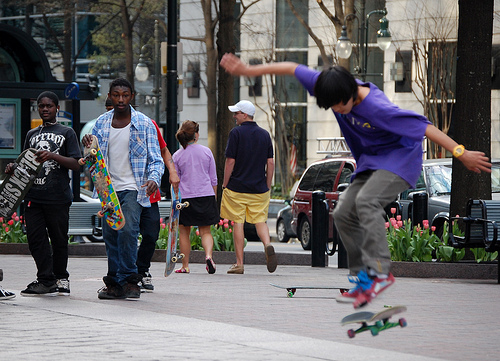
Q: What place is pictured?
A: It is a sidewalk.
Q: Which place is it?
A: It is a sidewalk.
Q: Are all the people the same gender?
A: No, they are both male and female.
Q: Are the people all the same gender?
A: No, they are both male and female.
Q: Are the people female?
A: No, they are both male and female.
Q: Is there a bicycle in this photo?
A: No, there are no bicycles.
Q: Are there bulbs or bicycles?
A: No, there are no bicycles or bulbs.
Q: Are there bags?
A: No, there are no bags.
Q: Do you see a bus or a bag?
A: No, there are no bags or buses.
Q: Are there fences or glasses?
A: No, there are no fences or glasses.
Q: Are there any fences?
A: No, there are no fences.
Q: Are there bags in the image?
A: No, there are no bags.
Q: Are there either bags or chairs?
A: No, there are no bags or chairs.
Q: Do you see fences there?
A: No, there are no fences.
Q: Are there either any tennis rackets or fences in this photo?
A: No, there are no fences or tennis rackets.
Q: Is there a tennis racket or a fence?
A: No, there are no fences or rackets.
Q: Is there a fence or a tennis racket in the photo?
A: No, there are no fences or rackets.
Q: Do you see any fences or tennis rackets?
A: No, there are no fences or tennis rackets.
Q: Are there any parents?
A: No, there are no parents.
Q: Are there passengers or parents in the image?
A: No, there are no parents or passengers.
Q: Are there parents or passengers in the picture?
A: No, there are no parents or passengers.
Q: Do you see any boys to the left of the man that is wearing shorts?
A: Yes, there is a boy to the left of the man.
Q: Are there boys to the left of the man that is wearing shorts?
A: Yes, there is a boy to the left of the man.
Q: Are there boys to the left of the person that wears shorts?
A: Yes, there is a boy to the left of the man.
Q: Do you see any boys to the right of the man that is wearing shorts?
A: No, the boy is to the left of the man.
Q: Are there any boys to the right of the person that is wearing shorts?
A: No, the boy is to the left of the man.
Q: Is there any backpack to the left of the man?
A: No, there is a boy to the left of the man.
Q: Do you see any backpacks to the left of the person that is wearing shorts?
A: No, there is a boy to the left of the man.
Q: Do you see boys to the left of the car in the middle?
A: Yes, there is a boy to the left of the car.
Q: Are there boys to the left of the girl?
A: Yes, there is a boy to the left of the girl.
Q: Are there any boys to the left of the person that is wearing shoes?
A: Yes, there is a boy to the left of the girl.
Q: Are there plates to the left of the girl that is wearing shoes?
A: No, there is a boy to the left of the girl.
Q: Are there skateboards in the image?
A: Yes, there is a skateboard.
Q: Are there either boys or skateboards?
A: Yes, there is a skateboard.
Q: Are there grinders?
A: No, there are no grinders.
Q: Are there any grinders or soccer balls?
A: No, there are no grinders or soccer balls.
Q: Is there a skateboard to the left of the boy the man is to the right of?
A: Yes, there is a skateboard to the left of the boy.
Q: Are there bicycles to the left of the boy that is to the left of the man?
A: No, there is a skateboard to the left of the boy.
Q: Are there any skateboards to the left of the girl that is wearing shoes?
A: Yes, there is a skateboard to the left of the girl.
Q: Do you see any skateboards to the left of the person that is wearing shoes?
A: Yes, there is a skateboard to the left of the girl.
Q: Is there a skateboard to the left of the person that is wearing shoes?
A: Yes, there is a skateboard to the left of the girl.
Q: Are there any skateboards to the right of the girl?
A: No, the skateboard is to the left of the girl.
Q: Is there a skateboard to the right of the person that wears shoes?
A: No, the skateboard is to the left of the girl.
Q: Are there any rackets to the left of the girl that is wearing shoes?
A: No, there is a skateboard to the left of the girl.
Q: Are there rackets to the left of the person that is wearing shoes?
A: No, there is a skateboard to the left of the girl.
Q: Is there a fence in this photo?
A: No, there are no fences.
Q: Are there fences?
A: No, there are no fences.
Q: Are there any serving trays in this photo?
A: No, there are no serving trays.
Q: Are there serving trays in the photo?
A: No, there are no serving trays.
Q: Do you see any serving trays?
A: No, there are no serving trays.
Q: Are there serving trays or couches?
A: No, there are no serving trays or couches.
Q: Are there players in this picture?
A: No, there are no players.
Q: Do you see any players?
A: No, there are no players.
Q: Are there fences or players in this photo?
A: No, there are no players or fences.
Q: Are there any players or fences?
A: No, there are no players or fences.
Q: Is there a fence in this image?
A: No, there are no fences.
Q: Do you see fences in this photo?
A: No, there are no fences.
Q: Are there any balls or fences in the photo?
A: No, there are no fences or balls.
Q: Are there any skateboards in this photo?
A: Yes, there is a skateboard.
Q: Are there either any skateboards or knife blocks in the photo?
A: Yes, there is a skateboard.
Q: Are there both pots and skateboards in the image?
A: No, there is a skateboard but no pots.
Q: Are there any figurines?
A: No, there are no figurines.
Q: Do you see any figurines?
A: No, there are no figurines.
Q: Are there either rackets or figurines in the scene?
A: No, there are no figurines or rackets.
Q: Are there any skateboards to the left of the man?
A: Yes, there is a skateboard to the left of the man.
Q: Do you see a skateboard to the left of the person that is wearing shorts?
A: Yes, there is a skateboard to the left of the man.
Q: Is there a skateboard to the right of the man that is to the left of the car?
A: No, the skateboard is to the left of the man.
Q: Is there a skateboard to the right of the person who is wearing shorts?
A: No, the skateboard is to the left of the man.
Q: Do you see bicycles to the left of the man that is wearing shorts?
A: No, there is a skateboard to the left of the man.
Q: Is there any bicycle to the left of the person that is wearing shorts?
A: No, there is a skateboard to the left of the man.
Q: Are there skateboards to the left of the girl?
A: Yes, there is a skateboard to the left of the girl.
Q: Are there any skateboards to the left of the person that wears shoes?
A: Yes, there is a skateboard to the left of the girl.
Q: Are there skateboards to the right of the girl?
A: No, the skateboard is to the left of the girl.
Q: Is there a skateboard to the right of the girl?
A: No, the skateboard is to the left of the girl.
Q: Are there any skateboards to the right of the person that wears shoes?
A: No, the skateboard is to the left of the girl.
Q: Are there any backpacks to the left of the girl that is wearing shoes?
A: No, there is a skateboard to the left of the girl.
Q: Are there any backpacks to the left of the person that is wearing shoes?
A: No, there is a skateboard to the left of the girl.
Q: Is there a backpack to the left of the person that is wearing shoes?
A: No, there is a skateboard to the left of the girl.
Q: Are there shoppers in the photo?
A: No, there are no shoppers.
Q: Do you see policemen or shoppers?
A: No, there are no shoppers or policemen.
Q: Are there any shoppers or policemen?
A: No, there are no shoppers or policemen.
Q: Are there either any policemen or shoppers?
A: No, there are no shoppers or policemen.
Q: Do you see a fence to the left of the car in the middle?
A: No, there is a man to the left of the car.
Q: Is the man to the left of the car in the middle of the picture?
A: Yes, the man is to the left of the car.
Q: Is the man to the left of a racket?
A: No, the man is to the left of the car.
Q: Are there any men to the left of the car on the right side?
A: Yes, there is a man to the left of the car.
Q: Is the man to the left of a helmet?
A: No, the man is to the left of the car.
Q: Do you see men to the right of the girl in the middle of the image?
A: Yes, there is a man to the right of the girl.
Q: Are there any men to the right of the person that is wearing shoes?
A: Yes, there is a man to the right of the girl.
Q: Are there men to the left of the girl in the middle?
A: No, the man is to the right of the girl.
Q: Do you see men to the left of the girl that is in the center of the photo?
A: No, the man is to the right of the girl.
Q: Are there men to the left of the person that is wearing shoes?
A: No, the man is to the right of the girl.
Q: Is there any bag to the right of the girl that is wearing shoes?
A: No, there is a man to the right of the girl.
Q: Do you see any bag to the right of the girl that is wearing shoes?
A: No, there is a man to the right of the girl.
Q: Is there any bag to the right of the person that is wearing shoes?
A: No, there is a man to the right of the girl.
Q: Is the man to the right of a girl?
A: Yes, the man is to the right of a girl.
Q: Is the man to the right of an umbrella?
A: No, the man is to the right of a girl.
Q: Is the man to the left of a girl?
A: No, the man is to the right of a girl.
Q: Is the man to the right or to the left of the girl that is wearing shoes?
A: The man is to the right of the girl.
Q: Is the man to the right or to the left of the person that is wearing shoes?
A: The man is to the right of the girl.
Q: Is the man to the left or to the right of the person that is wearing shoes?
A: The man is to the right of the girl.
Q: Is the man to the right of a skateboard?
A: Yes, the man is to the right of a skateboard.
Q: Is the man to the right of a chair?
A: No, the man is to the right of a skateboard.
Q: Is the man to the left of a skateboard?
A: No, the man is to the right of a skateboard.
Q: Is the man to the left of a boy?
A: No, the man is to the right of a boy.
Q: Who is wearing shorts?
A: The man is wearing shorts.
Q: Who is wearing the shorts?
A: The man is wearing shorts.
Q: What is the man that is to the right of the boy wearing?
A: The man is wearing shorts.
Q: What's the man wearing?
A: The man is wearing shorts.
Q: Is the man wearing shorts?
A: Yes, the man is wearing shorts.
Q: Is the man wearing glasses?
A: No, the man is wearing shorts.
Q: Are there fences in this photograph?
A: No, there are no fences.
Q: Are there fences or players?
A: No, there are no fences or players.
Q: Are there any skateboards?
A: Yes, there is a skateboard.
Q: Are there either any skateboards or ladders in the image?
A: Yes, there is a skateboard.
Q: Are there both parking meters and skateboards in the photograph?
A: No, there is a skateboard but no parking meters.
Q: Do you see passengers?
A: No, there are no passengers.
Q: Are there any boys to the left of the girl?
A: Yes, there is a boy to the left of the girl.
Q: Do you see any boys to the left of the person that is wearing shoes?
A: Yes, there is a boy to the left of the girl.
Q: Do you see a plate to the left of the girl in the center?
A: No, there is a boy to the left of the girl.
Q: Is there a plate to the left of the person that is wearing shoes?
A: No, there is a boy to the left of the girl.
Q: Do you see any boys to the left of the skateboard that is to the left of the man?
A: Yes, there is a boy to the left of the skateboard.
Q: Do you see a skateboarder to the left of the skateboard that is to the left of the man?
A: No, there is a boy to the left of the skateboard.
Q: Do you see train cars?
A: No, there are no train cars.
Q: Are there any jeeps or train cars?
A: No, there are no train cars or jeeps.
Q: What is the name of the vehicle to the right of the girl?
A: The vehicle is a car.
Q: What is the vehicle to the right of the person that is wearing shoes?
A: The vehicle is a car.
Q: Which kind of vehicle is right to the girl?
A: The vehicle is a car.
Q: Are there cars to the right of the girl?
A: Yes, there is a car to the right of the girl.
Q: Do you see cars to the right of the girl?
A: Yes, there is a car to the right of the girl.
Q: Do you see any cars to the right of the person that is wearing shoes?
A: Yes, there is a car to the right of the girl.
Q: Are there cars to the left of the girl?
A: No, the car is to the right of the girl.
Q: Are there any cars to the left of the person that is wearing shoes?
A: No, the car is to the right of the girl.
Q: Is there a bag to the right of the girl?
A: No, there is a car to the right of the girl.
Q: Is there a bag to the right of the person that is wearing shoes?
A: No, there is a car to the right of the girl.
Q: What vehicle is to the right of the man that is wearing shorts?
A: The vehicle is a car.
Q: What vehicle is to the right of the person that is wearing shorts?
A: The vehicle is a car.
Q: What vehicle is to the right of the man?
A: The vehicle is a car.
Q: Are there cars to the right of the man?
A: Yes, there is a car to the right of the man.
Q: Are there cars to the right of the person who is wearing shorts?
A: Yes, there is a car to the right of the man.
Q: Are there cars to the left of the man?
A: No, the car is to the right of the man.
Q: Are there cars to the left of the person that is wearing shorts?
A: No, the car is to the right of the man.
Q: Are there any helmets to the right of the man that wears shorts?
A: No, there is a car to the right of the man.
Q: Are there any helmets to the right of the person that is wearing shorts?
A: No, there is a car to the right of the man.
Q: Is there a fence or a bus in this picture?
A: No, there are no fences or buses.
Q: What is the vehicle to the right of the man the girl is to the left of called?
A: The vehicle is a car.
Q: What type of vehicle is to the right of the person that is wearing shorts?
A: The vehicle is a car.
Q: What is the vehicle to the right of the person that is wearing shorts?
A: The vehicle is a car.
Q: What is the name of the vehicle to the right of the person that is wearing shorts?
A: The vehicle is a car.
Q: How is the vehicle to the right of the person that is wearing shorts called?
A: The vehicle is a car.